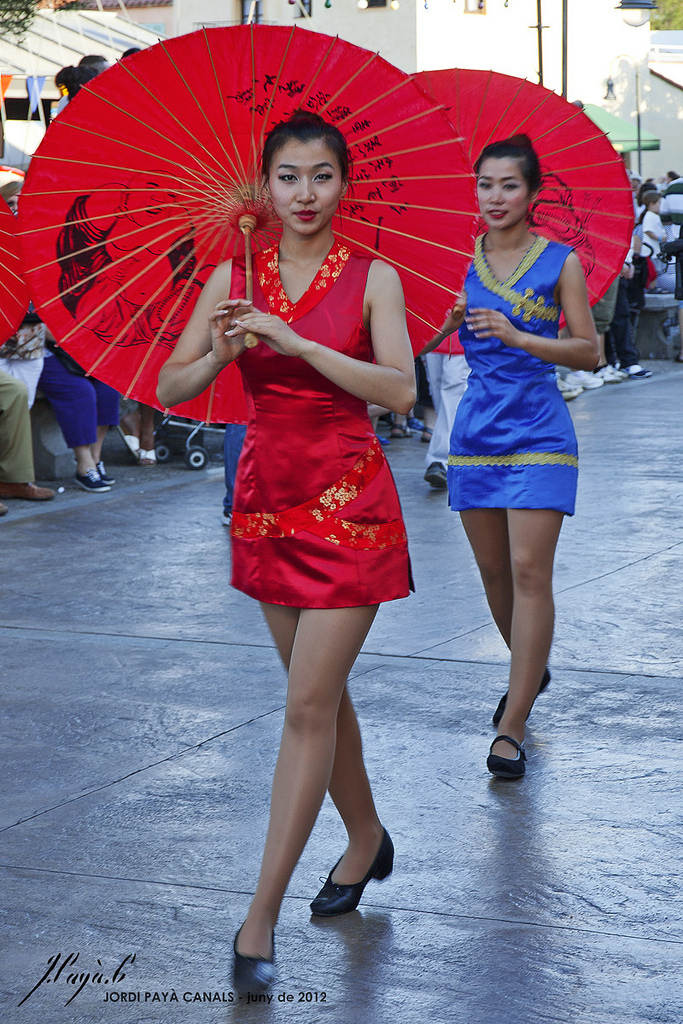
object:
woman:
[158, 101, 419, 994]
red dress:
[226, 236, 414, 608]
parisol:
[407, 68, 635, 358]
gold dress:
[444, 233, 577, 513]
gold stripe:
[504, 233, 550, 291]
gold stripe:
[472, 235, 558, 325]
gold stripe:
[444, 451, 578, 468]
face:
[267, 109, 345, 237]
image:
[55, 164, 220, 355]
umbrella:
[18, 20, 483, 423]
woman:
[419, 131, 599, 780]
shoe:
[310, 822, 393, 917]